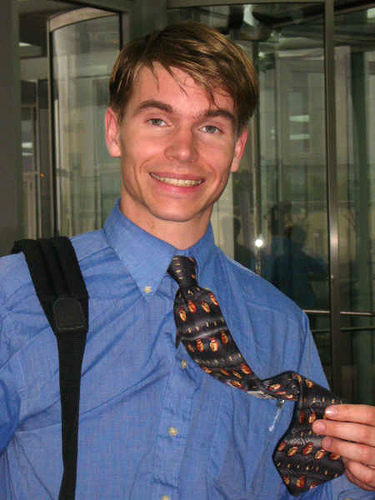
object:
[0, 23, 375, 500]
man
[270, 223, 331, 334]
reflection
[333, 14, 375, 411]
window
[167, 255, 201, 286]
knot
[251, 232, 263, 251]
light reflection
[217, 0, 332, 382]
window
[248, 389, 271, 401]
brand logo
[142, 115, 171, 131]
eye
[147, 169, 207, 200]
mouth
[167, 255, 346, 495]
tie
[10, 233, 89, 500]
strap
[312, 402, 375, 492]
hand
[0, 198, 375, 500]
shirt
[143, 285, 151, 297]
button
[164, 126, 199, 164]
nose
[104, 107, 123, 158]
ear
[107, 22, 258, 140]
hair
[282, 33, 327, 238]
window